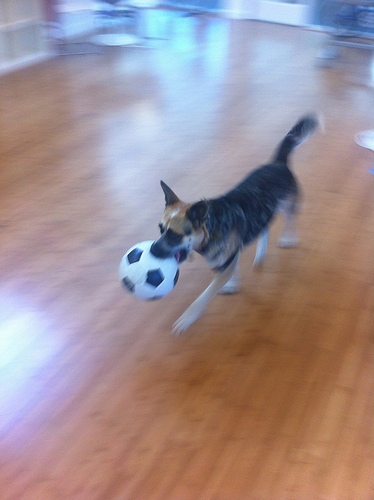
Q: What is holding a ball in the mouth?
A: A dog is holding a ball in the mouth.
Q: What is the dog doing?
A: The dog is running across the floor.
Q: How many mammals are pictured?
A: One.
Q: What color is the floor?
A: Brown.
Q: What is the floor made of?
A: Wood.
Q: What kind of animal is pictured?
A: Dog.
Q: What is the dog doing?
A: Carrying a soccer ball.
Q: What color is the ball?
A: Black and white.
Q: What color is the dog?
A: Brown, black and white.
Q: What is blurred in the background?
A: Chairs.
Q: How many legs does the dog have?
A: Four.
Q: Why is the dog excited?
A: Playing with soccer ball.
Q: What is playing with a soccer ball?
A: A happy dog.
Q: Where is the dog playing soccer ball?
A: On a wooden floor.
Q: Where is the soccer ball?
A: In dog's mouth.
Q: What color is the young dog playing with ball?
A: Tan, white and black mixed breed.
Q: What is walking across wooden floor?
A: The dog.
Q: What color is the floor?
A: Light brown.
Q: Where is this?
A: A dance studio.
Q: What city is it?
A: Boston.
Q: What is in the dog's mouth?
A: A ball.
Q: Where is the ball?
A: The dog's mouth.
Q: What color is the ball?
A: Black and white.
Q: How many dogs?
A: 1.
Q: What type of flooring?
A: Wood.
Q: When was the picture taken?
A: Daytime.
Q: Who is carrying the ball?
A: The dog.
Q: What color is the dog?
A: Black, brown, and white.